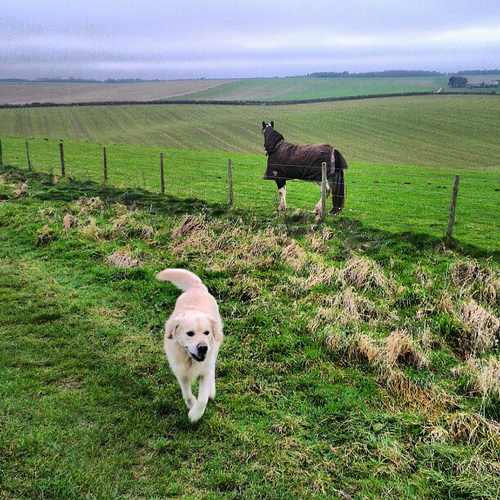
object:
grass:
[311, 258, 413, 369]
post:
[190, 176, 195, 217]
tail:
[328, 147, 349, 214]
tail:
[158, 268, 209, 292]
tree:
[442, 123, 463, 136]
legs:
[275, 175, 286, 204]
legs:
[316, 175, 332, 207]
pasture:
[0, 14, 500, 500]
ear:
[165, 313, 186, 340]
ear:
[208, 317, 222, 342]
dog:
[154, 267, 223, 423]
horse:
[260, 120, 349, 214]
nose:
[196, 341, 208, 357]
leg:
[171, 365, 192, 394]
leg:
[196, 348, 216, 404]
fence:
[0, 140, 460, 244]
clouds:
[0, 26, 500, 53]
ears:
[262, 121, 267, 129]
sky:
[0, 0, 500, 81]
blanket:
[269, 140, 331, 180]